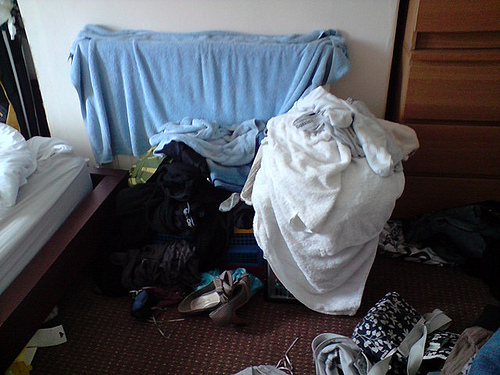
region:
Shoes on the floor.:
[171, 266, 264, 334]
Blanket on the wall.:
[60, 30, 345, 152]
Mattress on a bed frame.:
[0, 146, 130, 373]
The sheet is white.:
[0, 145, 102, 273]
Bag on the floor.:
[357, 285, 455, 373]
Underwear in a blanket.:
[291, 97, 383, 182]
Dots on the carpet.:
[109, 340, 171, 370]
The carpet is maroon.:
[93, 326, 278, 372]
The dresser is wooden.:
[399, 0, 498, 211]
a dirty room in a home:
[32, 15, 452, 367]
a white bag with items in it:
[234, 99, 425, 312]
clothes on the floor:
[105, 145, 283, 335]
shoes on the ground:
[180, 261, 262, 331]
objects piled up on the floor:
[266, 296, 498, 374]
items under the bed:
[4, 286, 71, 373]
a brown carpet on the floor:
[76, 308, 221, 374]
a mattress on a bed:
[2, 4, 105, 246]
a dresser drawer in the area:
[403, 9, 496, 201]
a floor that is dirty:
[115, 123, 455, 351]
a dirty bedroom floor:
[99, 128, 471, 365]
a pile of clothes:
[148, 103, 328, 351]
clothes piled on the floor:
[132, 114, 321, 336]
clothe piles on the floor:
[73, 25, 375, 354]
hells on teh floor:
[180, 256, 350, 346]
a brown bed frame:
[2, 119, 201, 283]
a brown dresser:
[397, 16, 496, 197]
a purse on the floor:
[342, 276, 475, 368]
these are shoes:
[201, 265, 261, 329]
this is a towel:
[284, 141, 373, 313]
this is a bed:
[35, 196, 113, 272]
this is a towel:
[76, 31, 341, 85]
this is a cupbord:
[408, 10, 495, 202]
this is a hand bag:
[380, 296, 444, 353]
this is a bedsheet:
[14, 168, 74, 243]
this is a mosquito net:
[1, 147, 40, 206]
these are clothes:
[117, 178, 213, 277]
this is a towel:
[168, 115, 250, 152]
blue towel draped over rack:
[94, 25, 347, 128]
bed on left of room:
[5, 131, 76, 370]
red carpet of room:
[119, 296, 344, 371]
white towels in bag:
[262, 81, 371, 324]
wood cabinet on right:
[409, 31, 498, 185]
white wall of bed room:
[29, 7, 364, 156]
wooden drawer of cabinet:
[406, 6, 491, 43]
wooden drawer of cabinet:
[399, 62, 499, 119]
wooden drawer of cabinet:
[394, 126, 498, 183]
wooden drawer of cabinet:
[395, 178, 498, 217]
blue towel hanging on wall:
[66, 21, 353, 192]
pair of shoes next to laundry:
[175, 269, 257, 326]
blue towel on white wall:
[67, 20, 342, 167]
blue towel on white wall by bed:
[12, 17, 379, 249]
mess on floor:
[77, 28, 469, 355]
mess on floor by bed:
[0, 92, 441, 303]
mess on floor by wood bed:
[13, 97, 426, 363]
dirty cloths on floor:
[121, 104, 456, 364]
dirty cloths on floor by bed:
[1, 87, 445, 346]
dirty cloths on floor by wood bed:
[3, 81, 435, 298]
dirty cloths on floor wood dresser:
[239, 27, 496, 318]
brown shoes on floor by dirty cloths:
[127, 239, 291, 354]